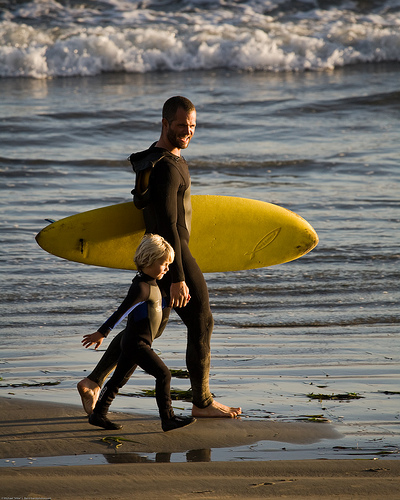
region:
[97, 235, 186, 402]
The boy is young.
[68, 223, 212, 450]
The boy is walking.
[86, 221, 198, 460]
The boy is wearing a wet suit.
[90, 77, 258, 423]
The man is walking.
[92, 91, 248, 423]
The man is wearing a wet sui.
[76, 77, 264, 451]
They are holding hands.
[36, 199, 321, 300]
The board is yellow.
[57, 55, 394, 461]
They are on the shore.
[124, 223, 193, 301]
He has blond hair.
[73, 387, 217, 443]
He has black shoes on.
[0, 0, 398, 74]
wave in the water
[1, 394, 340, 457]
sand next to water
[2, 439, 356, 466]
small channel of water running through the sand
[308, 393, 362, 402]
small piles of seaweed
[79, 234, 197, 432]
boy with blond hair is walking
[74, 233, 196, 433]
boy on brown sand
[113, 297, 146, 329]
white stripe on boy's sleeve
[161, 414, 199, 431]
boy is wearing brown shoes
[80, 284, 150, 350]
boys arm is outstretched behind him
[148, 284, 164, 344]
light brown panel on front of wet suit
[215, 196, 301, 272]
the board is yellow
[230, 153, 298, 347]
the board is yellow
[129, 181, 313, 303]
the board is yellow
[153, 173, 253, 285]
the board is yellow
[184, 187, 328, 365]
the board is yellow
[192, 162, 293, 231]
the board is yellow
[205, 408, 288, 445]
the sand is brown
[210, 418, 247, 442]
the sand is brown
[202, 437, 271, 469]
the sand is brown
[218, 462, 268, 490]
the sand is brown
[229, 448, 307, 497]
the sand is brown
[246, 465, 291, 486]
the sand is brown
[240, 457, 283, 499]
the sand is brown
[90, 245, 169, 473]
this is a girl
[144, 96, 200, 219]
this is a man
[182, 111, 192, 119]
the man is light skinned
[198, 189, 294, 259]
this is a surf board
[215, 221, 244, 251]
the board is yellow in color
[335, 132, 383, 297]
this is a water body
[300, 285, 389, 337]
the water is calm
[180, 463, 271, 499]
this is the beach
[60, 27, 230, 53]
these are the waves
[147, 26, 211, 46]
the waves are white in color